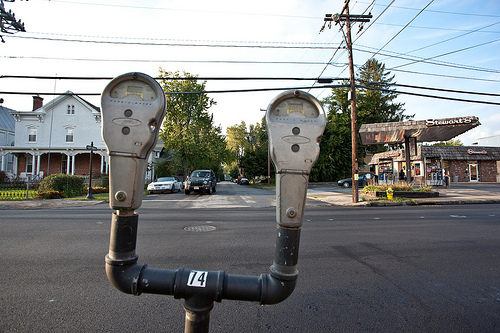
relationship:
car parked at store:
[338, 171, 374, 190] [372, 145, 499, 186]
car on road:
[143, 172, 180, 194] [151, 165, 327, 212]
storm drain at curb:
[422, 200, 442, 209] [360, 196, 500, 209]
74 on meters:
[187, 269, 208, 291] [104, 75, 328, 333]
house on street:
[1, 89, 108, 190] [3, 200, 499, 332]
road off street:
[151, 165, 327, 212] [3, 200, 499, 332]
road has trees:
[151, 165, 327, 212] [160, 73, 276, 176]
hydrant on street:
[386, 184, 397, 202] [3, 200, 499, 332]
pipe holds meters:
[106, 212, 297, 330] [104, 75, 328, 333]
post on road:
[266, 142, 271, 184] [151, 165, 327, 212]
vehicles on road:
[151, 169, 223, 190] [151, 165, 327, 212]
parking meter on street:
[99, 70, 164, 210] [3, 200, 499, 332]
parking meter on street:
[266, 89, 328, 228] [3, 200, 499, 332]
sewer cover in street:
[184, 219, 219, 236] [3, 200, 499, 332]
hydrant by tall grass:
[386, 183, 397, 203] [364, 173, 436, 193]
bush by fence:
[50, 170, 91, 200] [2, 179, 82, 203]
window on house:
[63, 128, 76, 145] [1, 89, 108, 190]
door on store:
[470, 160, 479, 184] [372, 145, 499, 186]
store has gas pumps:
[372, 145, 499, 186] [354, 119, 478, 184]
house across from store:
[1, 89, 108, 190] [372, 145, 499, 186]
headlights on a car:
[149, 181, 175, 191] [143, 172, 180, 194]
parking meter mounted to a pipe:
[99, 70, 164, 210] [106, 212, 297, 330]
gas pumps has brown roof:
[354, 119, 478, 184] [363, 114, 481, 147]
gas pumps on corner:
[354, 119, 478, 184] [303, 162, 442, 224]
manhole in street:
[184, 219, 219, 236] [3, 200, 499, 332]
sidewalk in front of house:
[2, 199, 104, 207] [1, 89, 108, 190]